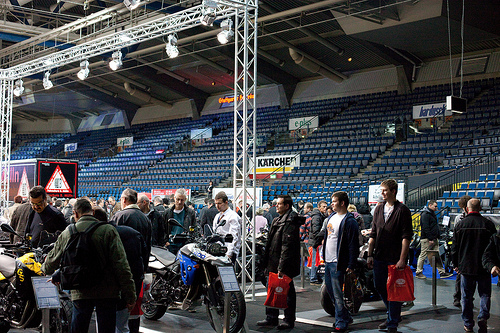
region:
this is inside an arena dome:
[25, 46, 415, 315]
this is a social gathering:
[41, 154, 334, 306]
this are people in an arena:
[260, 166, 390, 332]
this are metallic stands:
[218, 71, 313, 253]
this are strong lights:
[35, 68, 130, 102]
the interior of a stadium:
[0, 0, 495, 330]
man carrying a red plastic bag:
[375, 180, 412, 315]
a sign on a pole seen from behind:
[416, 240, 446, 310]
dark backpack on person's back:
[51, 215, 117, 295]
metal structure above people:
[0, 0, 260, 295]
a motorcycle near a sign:
[0, 216, 65, 326]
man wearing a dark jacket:
[262, 205, 302, 275]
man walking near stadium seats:
[412, 180, 472, 286]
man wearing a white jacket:
[203, 205, 243, 260]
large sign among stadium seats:
[222, 142, 331, 199]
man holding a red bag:
[254, 194, 309, 331]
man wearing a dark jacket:
[265, 211, 327, 283]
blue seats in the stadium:
[323, 91, 385, 165]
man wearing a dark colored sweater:
[367, 200, 424, 272]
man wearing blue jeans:
[456, 266, 494, 331]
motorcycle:
[129, 217, 274, 329]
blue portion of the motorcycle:
[174, 244, 209, 279]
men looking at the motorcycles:
[152, 191, 258, 241]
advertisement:
[249, 148, 325, 181]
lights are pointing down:
[6, 16, 284, 101]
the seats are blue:
[340, 106, 412, 162]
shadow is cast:
[415, 295, 450, 326]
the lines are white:
[312, 300, 323, 326]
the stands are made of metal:
[227, 18, 288, 171]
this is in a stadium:
[13, 30, 446, 286]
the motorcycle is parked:
[157, 218, 270, 299]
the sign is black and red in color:
[43, 150, 103, 204]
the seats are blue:
[8, 130, 496, 214]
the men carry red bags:
[264, 260, 413, 310]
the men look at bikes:
[1, 179, 409, 329]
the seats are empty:
[11, 131, 498, 205]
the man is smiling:
[381, 185, 393, 200]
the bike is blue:
[148, 227, 245, 329]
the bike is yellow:
[0, 246, 77, 326]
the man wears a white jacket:
[213, 209, 242, 251]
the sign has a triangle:
[44, 162, 72, 194]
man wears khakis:
[416, 239, 448, 272]